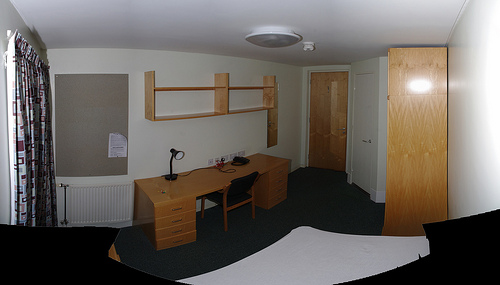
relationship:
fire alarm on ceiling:
[302, 41, 316, 51] [323, 7, 371, 62]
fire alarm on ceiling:
[301, 41, 316, 51] [12, 1, 460, 67]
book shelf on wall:
[137, 65, 279, 116] [43, 48, 303, 229]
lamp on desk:
[165, 147, 186, 180] [132, 148, 292, 247]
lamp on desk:
[157, 143, 189, 183] [134, 151, 285, 241]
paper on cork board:
[92, 139, 193, 186] [54, 73, 129, 177]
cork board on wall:
[52, 72, 129, 176] [43, 48, 303, 229]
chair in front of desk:
[223, 172, 259, 228] [135, 152, 290, 252]